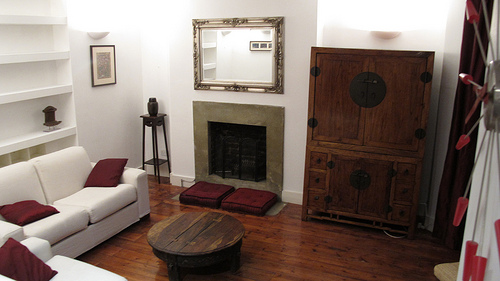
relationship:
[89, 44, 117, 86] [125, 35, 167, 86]
framed picture on wall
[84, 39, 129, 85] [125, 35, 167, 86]
framed picture on wall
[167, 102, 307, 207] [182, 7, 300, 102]
fireplace under mirror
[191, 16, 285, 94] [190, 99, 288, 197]
mirror above fireplace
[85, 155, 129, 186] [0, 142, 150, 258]
pillow on couch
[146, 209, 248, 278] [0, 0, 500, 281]
table in living room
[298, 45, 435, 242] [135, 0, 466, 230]
cabinet against wall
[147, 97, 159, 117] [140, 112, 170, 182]
vase on table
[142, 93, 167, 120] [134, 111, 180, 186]
vase on table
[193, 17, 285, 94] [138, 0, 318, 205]
mirror hanging on wall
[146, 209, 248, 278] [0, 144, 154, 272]
table in front of sofa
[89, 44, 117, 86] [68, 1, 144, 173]
framed picture on wall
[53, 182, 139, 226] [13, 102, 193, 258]
cushion on sofa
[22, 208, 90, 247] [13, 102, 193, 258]
cushion on sofa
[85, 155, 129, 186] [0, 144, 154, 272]
pillow on sofa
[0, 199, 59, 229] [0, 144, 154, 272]
pillow on sofa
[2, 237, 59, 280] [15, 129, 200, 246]
pillow on pillows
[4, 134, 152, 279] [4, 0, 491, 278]
couch in living room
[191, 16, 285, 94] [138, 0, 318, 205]
mirror on wall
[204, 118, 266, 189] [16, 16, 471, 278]
fireplace in living room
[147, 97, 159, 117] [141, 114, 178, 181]
vase on a stand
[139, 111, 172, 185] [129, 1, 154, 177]
stand in corner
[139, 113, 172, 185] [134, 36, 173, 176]
stand on corner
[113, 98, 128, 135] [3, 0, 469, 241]
part of a wall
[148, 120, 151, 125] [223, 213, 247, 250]
part of a table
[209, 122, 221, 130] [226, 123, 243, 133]
part of a part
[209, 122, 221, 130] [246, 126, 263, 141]
part of a part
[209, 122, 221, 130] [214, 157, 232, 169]
part of a part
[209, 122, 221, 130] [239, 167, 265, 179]
part of a part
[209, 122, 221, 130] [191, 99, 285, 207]
part of a fireplace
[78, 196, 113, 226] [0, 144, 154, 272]
part of a sofa